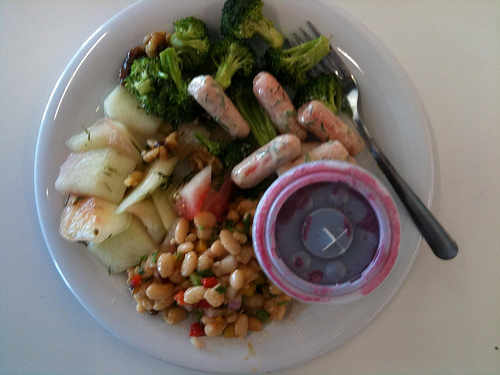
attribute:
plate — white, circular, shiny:
[32, 0, 436, 375]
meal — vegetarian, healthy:
[58, 0, 404, 350]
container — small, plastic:
[253, 161, 402, 306]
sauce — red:
[276, 179, 381, 287]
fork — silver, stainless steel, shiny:
[285, 18, 460, 263]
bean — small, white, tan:
[175, 216, 191, 244]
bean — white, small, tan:
[182, 249, 198, 280]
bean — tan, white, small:
[157, 251, 176, 281]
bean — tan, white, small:
[184, 285, 207, 305]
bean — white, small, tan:
[231, 267, 245, 292]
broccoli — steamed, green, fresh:
[221, 0, 286, 51]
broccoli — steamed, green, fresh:
[169, 15, 211, 71]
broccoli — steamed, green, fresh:
[209, 39, 257, 90]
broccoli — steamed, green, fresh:
[267, 37, 332, 90]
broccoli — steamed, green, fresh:
[293, 74, 343, 112]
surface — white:
[0, 0, 499, 375]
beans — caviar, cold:
[127, 211, 292, 350]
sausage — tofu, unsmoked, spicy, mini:
[189, 71, 251, 140]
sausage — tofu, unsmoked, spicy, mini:
[253, 70, 310, 141]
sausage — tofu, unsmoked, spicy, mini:
[232, 129, 304, 189]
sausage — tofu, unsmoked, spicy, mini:
[302, 98, 364, 158]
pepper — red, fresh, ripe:
[203, 276, 216, 289]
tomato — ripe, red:
[188, 322, 210, 338]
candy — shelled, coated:
[142, 32, 168, 57]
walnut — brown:
[118, 46, 146, 83]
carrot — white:
[117, 157, 188, 215]